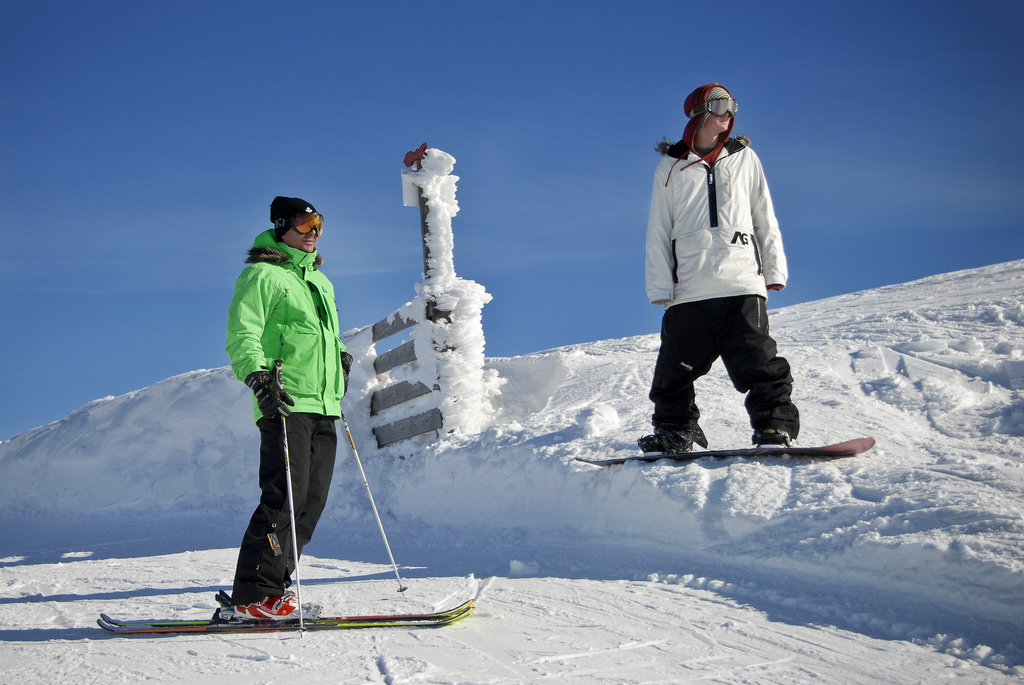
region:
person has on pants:
[221, 414, 339, 624]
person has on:
[649, 311, 799, 444]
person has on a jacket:
[638, 150, 791, 307]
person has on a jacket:
[272, 195, 317, 238]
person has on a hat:
[266, 198, 320, 234]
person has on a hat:
[657, 81, 747, 154]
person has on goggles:
[294, 217, 323, 231]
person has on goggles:
[705, 98, 737, 117]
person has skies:
[339, 420, 410, 592]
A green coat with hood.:
[229, 226, 346, 422]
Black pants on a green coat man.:
[231, 419, 340, 600]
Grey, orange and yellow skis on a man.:
[93, 602, 476, 637]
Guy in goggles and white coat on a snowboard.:
[648, 84, 797, 445]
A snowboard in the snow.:
[570, 435, 880, 465]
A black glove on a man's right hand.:
[245, 365, 296, 422]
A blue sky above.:
[0, 2, 1022, 424]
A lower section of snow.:
[3, 517, 1016, 682]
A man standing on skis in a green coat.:
[215, 192, 355, 626]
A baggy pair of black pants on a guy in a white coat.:
[646, 298, 801, 445]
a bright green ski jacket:
[221, 224, 357, 420]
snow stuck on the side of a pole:
[394, 137, 505, 457]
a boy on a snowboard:
[568, 77, 882, 473]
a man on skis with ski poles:
[92, 186, 484, 643]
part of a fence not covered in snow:
[353, 297, 452, 454]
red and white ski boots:
[212, 582, 321, 628]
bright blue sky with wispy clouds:
[0, 1, 1022, 441]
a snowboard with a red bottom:
[575, 431, 874, 469]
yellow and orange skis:
[92, 597, 481, 639]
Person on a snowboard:
[571, 39, 875, 472]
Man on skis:
[100, 184, 490, 636]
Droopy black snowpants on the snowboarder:
[641, 291, 801, 457]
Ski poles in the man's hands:
[269, 365, 415, 629]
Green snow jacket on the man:
[224, 224, 351, 427]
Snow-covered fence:
[329, 307, 446, 463]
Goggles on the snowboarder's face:
[695, 87, 738, 120]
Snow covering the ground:
[0, 250, 1022, 680]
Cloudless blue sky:
[0, 2, 1021, 446]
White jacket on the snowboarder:
[642, 133, 786, 314]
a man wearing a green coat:
[218, 264, 365, 394]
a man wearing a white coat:
[646, 143, 773, 318]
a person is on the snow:
[90, 200, 465, 638]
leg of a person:
[239, 419, 303, 582]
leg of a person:
[298, 419, 333, 560]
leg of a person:
[652, 303, 707, 440]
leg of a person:
[718, 314, 801, 444]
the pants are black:
[235, 412, 330, 609]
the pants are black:
[645, 308, 804, 436]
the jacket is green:
[234, 238, 342, 416]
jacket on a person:
[241, 232, 349, 411]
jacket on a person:
[643, 135, 789, 304]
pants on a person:
[649, 290, 804, 447]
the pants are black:
[643, 295, 795, 454]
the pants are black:
[239, 425, 338, 604]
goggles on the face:
[715, 97, 735, 114]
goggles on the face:
[289, 210, 322, 234]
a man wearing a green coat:
[245, 235, 356, 414]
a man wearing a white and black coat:
[651, 150, 776, 313]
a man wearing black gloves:
[248, 358, 294, 416]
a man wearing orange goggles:
[289, 212, 331, 233]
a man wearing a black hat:
[267, 193, 318, 238]